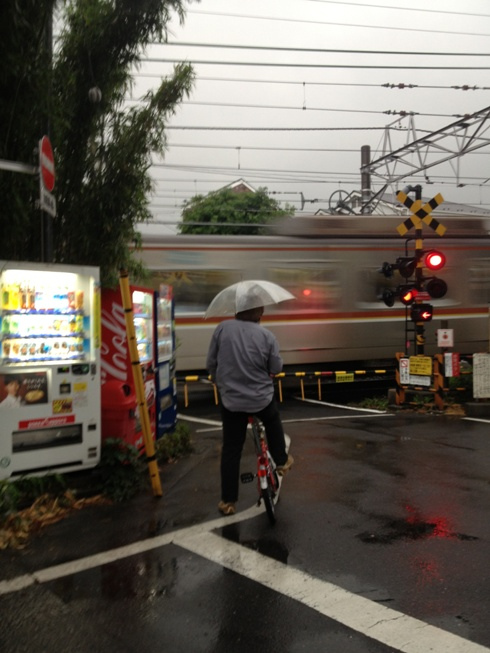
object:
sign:
[396, 189, 447, 238]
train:
[102, 214, 489, 379]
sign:
[38, 136, 58, 219]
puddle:
[347, 503, 479, 547]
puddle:
[322, 438, 408, 478]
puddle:
[45, 542, 224, 606]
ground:
[247, 593, 280, 617]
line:
[172, 529, 490, 652]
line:
[0, 412, 291, 593]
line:
[294, 397, 388, 414]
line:
[197, 413, 396, 433]